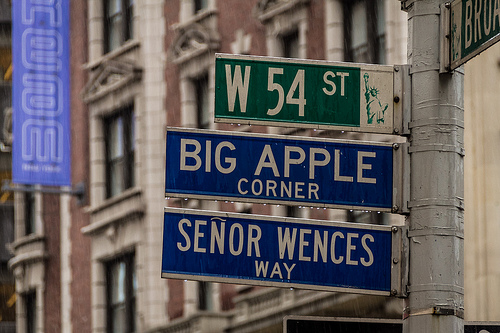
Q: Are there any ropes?
A: No, there are no ropes.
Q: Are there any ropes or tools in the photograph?
A: No, there are no ropes or tools.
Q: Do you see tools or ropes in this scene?
A: No, there are no ropes or tools.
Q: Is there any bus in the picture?
A: No, there are no buses.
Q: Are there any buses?
A: No, there are no buses.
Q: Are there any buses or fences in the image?
A: No, there are no buses or fences.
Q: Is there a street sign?
A: Yes, there is a street sign.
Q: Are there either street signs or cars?
A: Yes, there is a street sign.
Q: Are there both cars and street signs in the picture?
A: No, there is a street sign but no cars.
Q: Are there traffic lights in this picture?
A: No, there are no traffic lights.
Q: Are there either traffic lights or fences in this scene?
A: No, there are no traffic lights or fences.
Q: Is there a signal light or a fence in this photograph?
A: No, there are no traffic lights or fences.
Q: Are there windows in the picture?
A: Yes, there is a window.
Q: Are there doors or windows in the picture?
A: Yes, there is a window.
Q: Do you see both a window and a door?
A: No, there is a window but no doors.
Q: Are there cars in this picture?
A: No, there are no cars.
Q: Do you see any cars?
A: No, there are no cars.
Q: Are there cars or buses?
A: No, there are no cars or buses.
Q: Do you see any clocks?
A: No, there are no clocks.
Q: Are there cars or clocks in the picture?
A: No, there are no clocks or cars.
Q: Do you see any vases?
A: No, there are no vases.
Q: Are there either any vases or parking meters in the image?
A: No, there are no vases or parking meters.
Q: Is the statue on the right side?
A: Yes, the statue is on the right of the image.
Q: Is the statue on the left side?
A: No, the statue is on the right of the image.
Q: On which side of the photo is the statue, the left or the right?
A: The statue is on the right of the image.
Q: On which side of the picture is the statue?
A: The statue is on the right of the image.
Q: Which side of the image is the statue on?
A: The statue is on the right of the image.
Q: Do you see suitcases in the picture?
A: No, there are no suitcases.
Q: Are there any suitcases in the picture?
A: No, there are no suitcases.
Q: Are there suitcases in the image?
A: No, there are no suitcases.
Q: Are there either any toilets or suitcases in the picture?
A: No, there are no suitcases or toilets.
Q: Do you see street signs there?
A: Yes, there is a street sign.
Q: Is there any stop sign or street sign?
A: Yes, there is a street sign.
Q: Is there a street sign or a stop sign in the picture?
A: Yes, there is a street sign.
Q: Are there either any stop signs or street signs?
A: Yes, there is a street sign.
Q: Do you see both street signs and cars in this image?
A: No, there is a street sign but no cars.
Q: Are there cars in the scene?
A: No, there are no cars.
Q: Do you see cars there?
A: No, there are no cars.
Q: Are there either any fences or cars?
A: No, there are no cars or fences.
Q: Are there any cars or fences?
A: No, there are no cars or fences.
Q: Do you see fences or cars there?
A: No, there are no cars or fences.